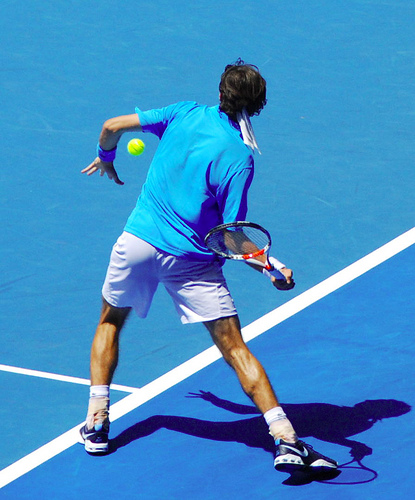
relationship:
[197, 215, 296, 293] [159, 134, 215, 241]
racquet behind back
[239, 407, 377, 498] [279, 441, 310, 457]
shoe has logo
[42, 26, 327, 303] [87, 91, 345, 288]
man playing tennis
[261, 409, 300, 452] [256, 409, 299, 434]
brace on ankle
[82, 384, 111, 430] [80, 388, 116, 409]
brace on ankle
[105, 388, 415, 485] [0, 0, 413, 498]
shadow on tennis court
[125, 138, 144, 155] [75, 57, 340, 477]
tennis ball in front of man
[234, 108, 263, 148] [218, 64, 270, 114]
band in hair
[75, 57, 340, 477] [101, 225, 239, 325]
man wearing shorts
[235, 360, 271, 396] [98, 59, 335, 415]
muscle on player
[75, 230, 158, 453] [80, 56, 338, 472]
leg of person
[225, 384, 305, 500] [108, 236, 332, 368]
leg of a person playing tennis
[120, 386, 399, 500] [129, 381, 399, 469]
shadow of a person playing tennis